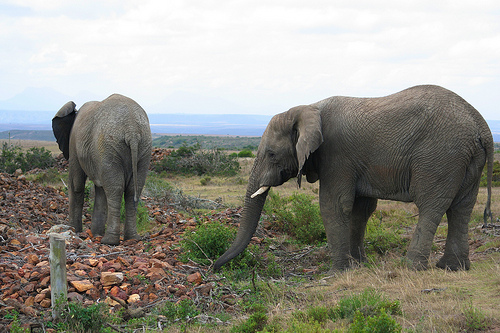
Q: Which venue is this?
A: This is a field.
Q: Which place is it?
A: It is a field.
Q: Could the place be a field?
A: Yes, it is a field.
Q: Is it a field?
A: Yes, it is a field.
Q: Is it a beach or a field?
A: It is a field.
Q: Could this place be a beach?
A: No, it is a field.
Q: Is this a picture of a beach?
A: No, the picture is showing a field.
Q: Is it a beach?
A: No, it is a field.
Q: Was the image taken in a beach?
A: No, the picture was taken in a field.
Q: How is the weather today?
A: It is cloudy.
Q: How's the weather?
A: It is cloudy.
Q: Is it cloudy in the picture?
A: Yes, it is cloudy.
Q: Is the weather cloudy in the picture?
A: Yes, it is cloudy.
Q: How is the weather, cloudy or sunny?
A: It is cloudy.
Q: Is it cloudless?
A: No, it is cloudy.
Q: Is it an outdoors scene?
A: Yes, it is outdoors.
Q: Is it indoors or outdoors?
A: It is outdoors.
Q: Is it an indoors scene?
A: No, it is outdoors.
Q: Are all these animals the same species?
A: Yes, all the animals are elephants.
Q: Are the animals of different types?
A: No, all the animals are elephants.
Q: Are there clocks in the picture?
A: No, there are no clocks.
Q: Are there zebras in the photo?
A: No, there are no zebras.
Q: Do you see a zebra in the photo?
A: No, there are no zebras.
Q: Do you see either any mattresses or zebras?
A: No, there are no zebras or mattresses.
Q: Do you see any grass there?
A: Yes, there is grass.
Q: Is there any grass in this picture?
A: Yes, there is grass.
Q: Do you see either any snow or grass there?
A: Yes, there is grass.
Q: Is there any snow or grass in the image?
A: Yes, there is grass.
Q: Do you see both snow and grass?
A: No, there is grass but no snow.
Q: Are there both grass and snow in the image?
A: No, there is grass but no snow.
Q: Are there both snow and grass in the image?
A: No, there is grass but no snow.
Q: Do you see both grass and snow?
A: No, there is grass but no snow.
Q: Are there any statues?
A: No, there are no statues.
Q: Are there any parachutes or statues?
A: No, there are no statues or parachutes.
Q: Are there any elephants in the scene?
A: Yes, there are elephants.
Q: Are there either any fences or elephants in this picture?
A: Yes, there are elephants.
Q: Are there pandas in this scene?
A: No, there are no pandas.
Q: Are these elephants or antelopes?
A: These are elephants.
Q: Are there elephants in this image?
A: Yes, there is an elephant.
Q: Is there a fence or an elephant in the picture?
A: Yes, there is an elephant.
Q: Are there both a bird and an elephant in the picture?
A: No, there is an elephant but no birds.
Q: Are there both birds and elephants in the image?
A: No, there is an elephant but no birds.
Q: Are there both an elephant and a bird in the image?
A: No, there is an elephant but no birds.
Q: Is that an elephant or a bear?
A: That is an elephant.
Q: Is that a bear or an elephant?
A: That is an elephant.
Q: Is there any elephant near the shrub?
A: Yes, there is an elephant near the shrub.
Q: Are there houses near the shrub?
A: No, there is an elephant near the shrub.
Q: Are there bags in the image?
A: No, there are no bags.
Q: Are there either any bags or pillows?
A: No, there are no bags or pillows.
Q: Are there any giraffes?
A: No, there are no giraffes.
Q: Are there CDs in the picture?
A: No, there are no cds.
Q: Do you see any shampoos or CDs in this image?
A: No, there are no CDs or shampoos.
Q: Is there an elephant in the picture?
A: Yes, there is an elephant.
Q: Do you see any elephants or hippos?
A: Yes, there is an elephant.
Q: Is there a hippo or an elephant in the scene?
A: Yes, there is an elephant.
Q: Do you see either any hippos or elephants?
A: Yes, there is an elephant.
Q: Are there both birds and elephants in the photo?
A: No, there is an elephant but no birds.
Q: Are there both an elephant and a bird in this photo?
A: No, there is an elephant but no birds.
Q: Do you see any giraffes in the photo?
A: No, there are no giraffes.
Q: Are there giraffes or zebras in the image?
A: No, there are no giraffes or zebras.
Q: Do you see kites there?
A: No, there are no kites.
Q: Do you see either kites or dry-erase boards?
A: No, there are no kites or dry-erase boards.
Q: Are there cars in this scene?
A: No, there are no cars.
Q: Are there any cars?
A: No, there are no cars.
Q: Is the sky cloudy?
A: Yes, the sky is cloudy.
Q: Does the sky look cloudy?
A: Yes, the sky is cloudy.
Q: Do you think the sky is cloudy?
A: Yes, the sky is cloudy.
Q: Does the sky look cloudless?
A: No, the sky is cloudy.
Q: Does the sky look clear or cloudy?
A: The sky is cloudy.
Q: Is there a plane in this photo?
A: No, there are no airplanes.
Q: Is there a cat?
A: No, there are no cats.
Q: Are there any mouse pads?
A: No, there are no mouse pads.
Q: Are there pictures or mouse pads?
A: No, there are no mouse pads or pictures.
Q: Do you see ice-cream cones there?
A: No, there are no ice-cream cones.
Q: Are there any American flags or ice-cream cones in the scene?
A: No, there are no ice-cream cones or American flags.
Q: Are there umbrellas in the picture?
A: No, there are no umbrellas.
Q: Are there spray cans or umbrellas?
A: No, there are no umbrellas or spray cans.